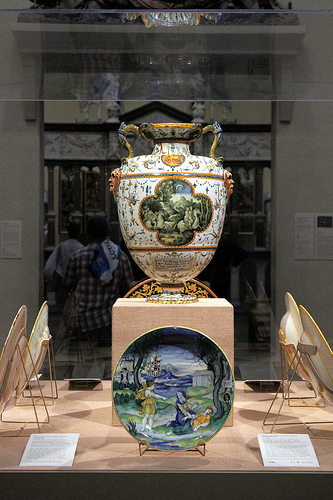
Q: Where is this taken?
A: In a shop.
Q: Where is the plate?
A: Near the front of the table.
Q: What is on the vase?
A: A painting.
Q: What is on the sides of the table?
A: Plates.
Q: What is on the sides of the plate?
A: Two Handles.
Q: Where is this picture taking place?
A: Museum.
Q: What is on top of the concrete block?
A: Vase.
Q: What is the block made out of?
A: Concrete.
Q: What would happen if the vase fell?
A: It would break.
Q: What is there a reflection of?
A: A couple of people.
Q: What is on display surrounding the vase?
A: Decorative plates.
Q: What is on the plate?
A: A painting.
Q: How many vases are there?
A: One.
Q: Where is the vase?
A: On block.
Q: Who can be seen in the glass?
A: People.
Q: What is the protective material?
A: Glass.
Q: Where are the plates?
A: Below the vase.